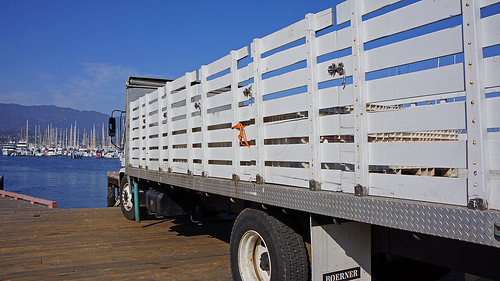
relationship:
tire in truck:
[112, 172, 143, 219] [106, 0, 497, 277]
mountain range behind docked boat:
[0, 102, 112, 129] [56, 124, 81, 161]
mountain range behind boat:
[0, 102, 112, 129] [70, 126, 82, 159]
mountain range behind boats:
[0, 102, 112, 129] [1, 135, 17, 156]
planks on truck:
[109, 80, 499, 221] [105, 62, 492, 242]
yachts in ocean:
[1, 119, 123, 157] [1, 152, 131, 206]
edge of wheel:
[238, 207, 304, 239] [224, 202, 304, 279]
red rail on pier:
[0, 186, 60, 209] [0, 185, 209, 280]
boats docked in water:
[0, 116, 118, 161] [2, 154, 121, 206]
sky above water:
[1, 1, 498, 120] [2, 154, 121, 206]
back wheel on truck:
[229, 206, 299, 279] [106, 0, 497, 277]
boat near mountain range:
[97, 122, 107, 156] [0, 102, 123, 141]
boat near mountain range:
[82, 127, 90, 155] [0, 102, 123, 141]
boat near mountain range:
[19, 118, 29, 155] [0, 102, 123, 141]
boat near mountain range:
[59, 126, 68, 156] [0, 102, 123, 141]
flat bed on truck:
[124, 85, 499, 242] [79, 64, 220, 239]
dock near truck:
[3, 137, 133, 237] [106, 0, 497, 277]